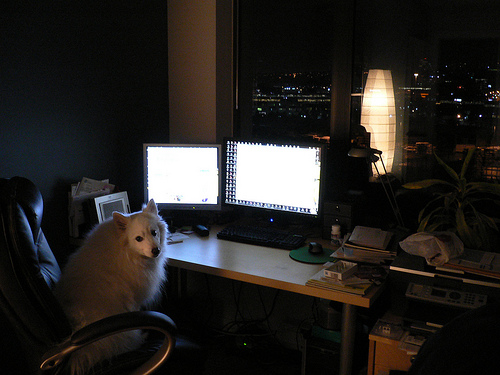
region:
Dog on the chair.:
[53, 192, 185, 372]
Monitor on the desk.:
[215, 120, 336, 245]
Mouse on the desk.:
[300, 235, 316, 255]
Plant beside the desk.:
[402, 136, 497, 247]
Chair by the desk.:
[0, 167, 201, 372]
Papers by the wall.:
[64, 170, 118, 239]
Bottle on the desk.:
[327, 220, 347, 247]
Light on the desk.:
[341, 130, 410, 236]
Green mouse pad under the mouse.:
[285, 233, 337, 269]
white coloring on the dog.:
[54, 195, 186, 372]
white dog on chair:
[1, 176, 188, 371]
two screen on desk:
[111, 123, 336, 256]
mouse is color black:
[285, 234, 332, 267]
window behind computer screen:
[219, 9, 499, 251]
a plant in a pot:
[397, 135, 495, 250]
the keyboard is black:
[211, 216, 308, 253]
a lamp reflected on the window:
[349, 54, 409, 190]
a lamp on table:
[339, 137, 418, 244]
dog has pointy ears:
[102, 197, 164, 227]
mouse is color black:
[189, 219, 212, 241]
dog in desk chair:
[78, 198, 163, 321]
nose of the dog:
[140, 238, 160, 256]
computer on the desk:
[214, 130, 331, 247]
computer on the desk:
[139, 139, 216, 222]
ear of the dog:
[108, 207, 128, 233]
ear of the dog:
[144, 201, 166, 219]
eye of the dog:
[145, 227, 159, 237]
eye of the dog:
[129, 233, 144, 241]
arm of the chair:
[70, 304, 177, 351]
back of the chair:
[0, 176, 57, 300]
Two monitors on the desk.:
[136, 127, 329, 218]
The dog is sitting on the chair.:
[69, 217, 164, 338]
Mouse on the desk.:
[304, 233, 325, 253]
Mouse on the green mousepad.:
[303, 234, 329, 270]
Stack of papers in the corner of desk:
[338, 218, 380, 270]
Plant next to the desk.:
[407, 133, 497, 254]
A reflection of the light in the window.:
[321, 57, 419, 193]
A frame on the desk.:
[90, 189, 142, 227]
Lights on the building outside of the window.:
[255, 49, 450, 141]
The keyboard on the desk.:
[223, 207, 313, 276]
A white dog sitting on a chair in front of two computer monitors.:
[47, 125, 338, 347]